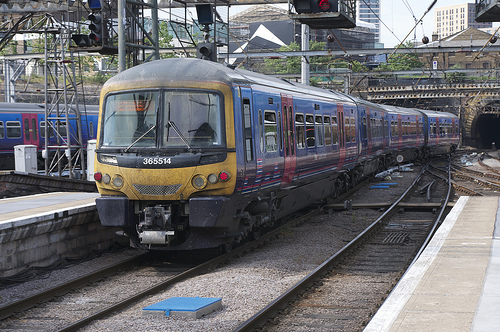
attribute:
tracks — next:
[63, 165, 454, 309]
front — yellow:
[75, 43, 263, 255]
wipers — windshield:
[106, 116, 219, 154]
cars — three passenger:
[54, 28, 463, 215]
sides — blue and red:
[201, 54, 471, 187]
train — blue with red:
[73, 39, 427, 259]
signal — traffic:
[275, 2, 365, 32]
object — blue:
[131, 287, 231, 317]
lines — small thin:
[163, 140, 403, 315]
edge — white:
[405, 254, 455, 328]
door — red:
[224, 78, 302, 218]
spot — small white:
[81, 269, 115, 314]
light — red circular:
[92, 158, 240, 202]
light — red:
[88, 143, 236, 211]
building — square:
[109, 3, 383, 69]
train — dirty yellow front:
[88, 52, 459, 264]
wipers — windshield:
[129, 109, 191, 147]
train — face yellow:
[61, 34, 474, 251]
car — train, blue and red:
[79, 50, 475, 224]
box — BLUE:
[139, 287, 219, 322]